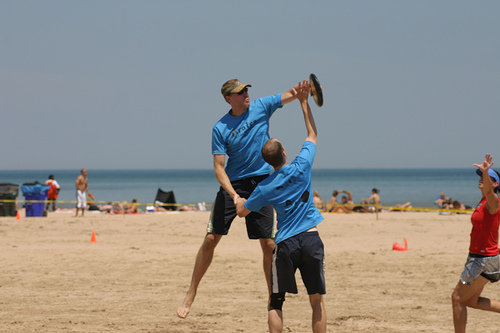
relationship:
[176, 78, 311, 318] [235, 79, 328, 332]
man fighting man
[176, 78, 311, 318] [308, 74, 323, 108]
man holding frisbee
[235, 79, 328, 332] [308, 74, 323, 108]
man grabbing at frisbee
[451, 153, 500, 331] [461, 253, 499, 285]
woman wearing shorts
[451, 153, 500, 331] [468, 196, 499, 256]
woman wearing shirt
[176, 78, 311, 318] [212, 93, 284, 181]
man wearing t shirt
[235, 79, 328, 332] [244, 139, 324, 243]
man wearing t shirt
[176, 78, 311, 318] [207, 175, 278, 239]
man wearing shorts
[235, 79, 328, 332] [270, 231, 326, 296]
man wearing shorts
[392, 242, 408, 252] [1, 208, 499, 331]
cone on beach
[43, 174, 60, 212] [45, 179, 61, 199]
person wearing shirt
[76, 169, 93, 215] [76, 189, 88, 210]
guy wearing pants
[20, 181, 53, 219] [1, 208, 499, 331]
recycle bin on beach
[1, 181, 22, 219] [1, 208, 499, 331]
trash bin on beach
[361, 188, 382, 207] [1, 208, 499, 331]
woman sitting on beach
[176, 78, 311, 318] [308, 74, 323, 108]
man playing with frisbee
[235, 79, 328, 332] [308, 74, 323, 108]
man playing with frisbee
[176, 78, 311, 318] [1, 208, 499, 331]
man jumping over beach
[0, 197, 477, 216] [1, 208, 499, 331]
crossing tape on beach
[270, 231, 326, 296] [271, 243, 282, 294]
shorts have stripe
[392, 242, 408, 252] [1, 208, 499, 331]
cone toppled on beach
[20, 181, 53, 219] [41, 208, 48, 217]
recycle bin has wheel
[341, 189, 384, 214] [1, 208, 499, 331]
guy laying on beach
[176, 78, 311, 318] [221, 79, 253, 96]
man wearing hat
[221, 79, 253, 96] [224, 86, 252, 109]
hat on head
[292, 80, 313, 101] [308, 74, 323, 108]
hand reaching for frisbee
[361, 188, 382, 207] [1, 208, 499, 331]
woman relaxing on beach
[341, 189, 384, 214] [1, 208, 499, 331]
guy relaxing on beach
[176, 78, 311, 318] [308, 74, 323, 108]
man jumping for frisbee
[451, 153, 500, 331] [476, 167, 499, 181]
woman wearing visor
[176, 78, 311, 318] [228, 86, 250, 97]
man wearing sunglasses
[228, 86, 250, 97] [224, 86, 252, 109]
sunglasses on head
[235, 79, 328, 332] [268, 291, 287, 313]
man wearing knee brace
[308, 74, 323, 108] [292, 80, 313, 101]
frisbee near hand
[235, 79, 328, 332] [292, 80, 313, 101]
man has hand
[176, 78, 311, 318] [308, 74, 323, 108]
man reaching for frisbee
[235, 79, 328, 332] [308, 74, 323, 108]
man reaching for frisbee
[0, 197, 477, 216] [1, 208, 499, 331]
crossing tape across beach